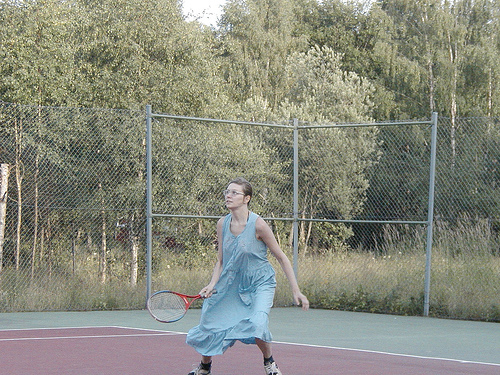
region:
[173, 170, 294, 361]
person wearing a dress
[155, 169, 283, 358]
person holding a tennis racket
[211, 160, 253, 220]
person wearing glasses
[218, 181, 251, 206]
person wearing eye glasses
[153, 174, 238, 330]
person holding tennis racket with right hand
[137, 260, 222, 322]
tennis racket is in right hand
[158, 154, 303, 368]
person playing tennis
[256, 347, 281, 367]
black sock on left foot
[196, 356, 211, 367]
black sock on right foot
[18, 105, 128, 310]
tall chain linked fence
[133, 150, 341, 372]
woman playing tennis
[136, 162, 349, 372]
woman holding a tennis racket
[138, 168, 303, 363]
woman wearing a dress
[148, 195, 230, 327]
tennis racket is in the right hand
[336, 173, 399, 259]
tall chain linked fence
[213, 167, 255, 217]
woman wearing glasses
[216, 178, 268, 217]
woman wearing eye glasses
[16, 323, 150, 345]
lines painted on ground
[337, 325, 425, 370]
white line painted on ground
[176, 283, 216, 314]
red handle of tennis racket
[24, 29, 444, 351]
this is on a tennis court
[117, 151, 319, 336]
the girl is playing tennis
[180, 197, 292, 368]
the girl is wearing a long dress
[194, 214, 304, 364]
the woman's dress is blue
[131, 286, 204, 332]
this is a tennis racket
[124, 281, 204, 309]
the tennis racket is multicolored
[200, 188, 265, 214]
the woman has glasses on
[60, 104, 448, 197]
this is a fence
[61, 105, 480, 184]
the fence is metal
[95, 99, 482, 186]
the fence is chain link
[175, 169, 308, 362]
a girl wearing a dress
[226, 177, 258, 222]
the head of a girl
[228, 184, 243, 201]
the face of a girl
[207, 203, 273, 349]
a long blue formal dress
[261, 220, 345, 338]
the left arm of a woman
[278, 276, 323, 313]
the left hand of a woman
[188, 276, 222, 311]
the right hand of a person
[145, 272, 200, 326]
a red and black tennis racket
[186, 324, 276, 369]
the legs of a woman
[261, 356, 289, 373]
the shoe of a woman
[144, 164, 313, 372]
woman in a blue dress playing tennis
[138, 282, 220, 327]
red and blue tennis racket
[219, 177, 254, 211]
woman is wearing glasses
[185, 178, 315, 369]
woman wearing a blue dress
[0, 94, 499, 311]
tall chain link fence around the tennis court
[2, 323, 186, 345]
white stripes define the court boundaries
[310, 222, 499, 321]
grass growing on the outside of the fence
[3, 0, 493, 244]
tall trees growing beyond the tennis court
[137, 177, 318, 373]
woman holding a tennis racket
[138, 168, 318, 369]
woman playing tennis in a dress